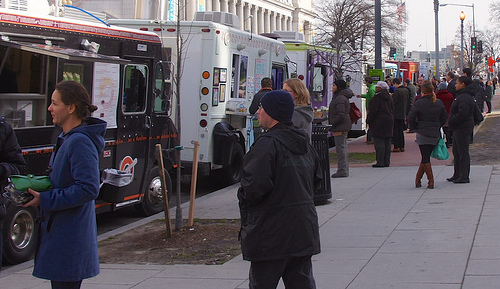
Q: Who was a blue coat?
A: The woman.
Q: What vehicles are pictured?
A: Large trucks.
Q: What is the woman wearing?
A: Blue jacket.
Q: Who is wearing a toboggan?
A: Man in front.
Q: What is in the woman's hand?
A: Green wallet.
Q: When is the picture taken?
A: Daytime.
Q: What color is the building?
A: White.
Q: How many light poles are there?
A: Two.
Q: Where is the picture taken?
A: Street.